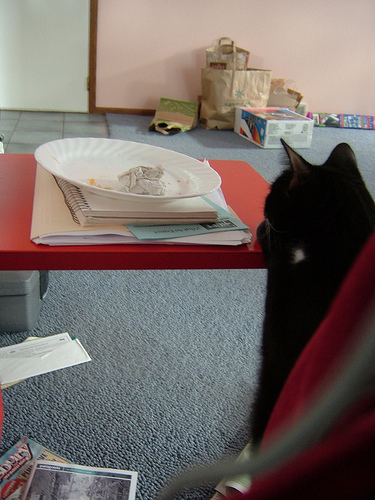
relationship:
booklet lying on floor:
[1, 432, 75, 498] [2, 106, 374, 498]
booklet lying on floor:
[21, 456, 139, 498] [2, 106, 374, 498]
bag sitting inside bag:
[202, 36, 255, 72] [200, 65, 274, 137]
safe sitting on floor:
[2, 267, 51, 330] [2, 106, 374, 498]